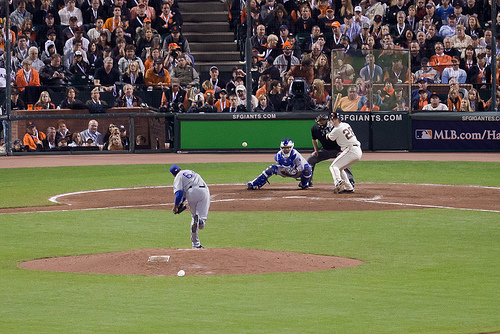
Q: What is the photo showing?
A: It is showing a stadium.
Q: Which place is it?
A: It is a stadium.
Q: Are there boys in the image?
A: No, there are no boys.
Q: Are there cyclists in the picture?
A: No, there are no cyclists.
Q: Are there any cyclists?
A: No, there are no cyclists.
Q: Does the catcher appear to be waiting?
A: Yes, the catcher is waiting.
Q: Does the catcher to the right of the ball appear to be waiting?
A: Yes, the catcher is waiting.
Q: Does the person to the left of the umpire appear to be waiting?
A: Yes, the catcher is waiting.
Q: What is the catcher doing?
A: The catcher is waiting.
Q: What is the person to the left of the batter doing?
A: The catcher is waiting.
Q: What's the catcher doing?
A: The catcher is waiting.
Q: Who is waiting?
A: The catcher is waiting.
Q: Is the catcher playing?
A: No, the catcher is waiting.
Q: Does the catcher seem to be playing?
A: No, the catcher is waiting.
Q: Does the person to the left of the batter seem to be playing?
A: No, the catcher is waiting.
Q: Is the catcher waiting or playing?
A: The catcher is waiting.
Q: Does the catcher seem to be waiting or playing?
A: The catcher is waiting.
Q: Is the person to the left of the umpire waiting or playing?
A: The catcher is waiting.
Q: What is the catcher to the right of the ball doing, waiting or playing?
A: The catcher is waiting.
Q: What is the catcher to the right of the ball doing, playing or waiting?
A: The catcher is waiting.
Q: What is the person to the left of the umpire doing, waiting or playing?
A: The catcher is waiting.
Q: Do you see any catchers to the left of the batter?
A: Yes, there is a catcher to the left of the batter.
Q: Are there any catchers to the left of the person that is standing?
A: Yes, there is a catcher to the left of the batter.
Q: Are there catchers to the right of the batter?
A: No, the catcher is to the left of the batter.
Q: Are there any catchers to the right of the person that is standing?
A: No, the catcher is to the left of the batter.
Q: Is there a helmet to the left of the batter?
A: No, there is a catcher to the left of the batter.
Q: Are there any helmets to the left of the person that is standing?
A: No, there is a catcher to the left of the batter.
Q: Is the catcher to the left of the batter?
A: Yes, the catcher is to the left of the batter.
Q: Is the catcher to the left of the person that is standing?
A: Yes, the catcher is to the left of the batter.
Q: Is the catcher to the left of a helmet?
A: No, the catcher is to the left of the batter.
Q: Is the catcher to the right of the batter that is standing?
A: No, the catcher is to the left of the batter.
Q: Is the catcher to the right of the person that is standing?
A: No, the catcher is to the left of the batter.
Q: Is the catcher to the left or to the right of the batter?
A: The catcher is to the left of the batter.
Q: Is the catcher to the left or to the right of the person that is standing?
A: The catcher is to the left of the batter.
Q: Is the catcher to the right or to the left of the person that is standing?
A: The catcher is to the left of the batter.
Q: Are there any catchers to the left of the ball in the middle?
A: No, the catcher is to the right of the ball.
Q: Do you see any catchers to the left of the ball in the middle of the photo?
A: No, the catcher is to the right of the ball.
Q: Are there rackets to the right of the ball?
A: No, there is a catcher to the right of the ball.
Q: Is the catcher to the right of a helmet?
A: No, the catcher is to the right of the ball.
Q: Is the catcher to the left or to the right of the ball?
A: The catcher is to the right of the ball.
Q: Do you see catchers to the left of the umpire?
A: Yes, there is a catcher to the left of the umpire.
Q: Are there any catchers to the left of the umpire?
A: Yes, there is a catcher to the left of the umpire.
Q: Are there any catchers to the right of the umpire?
A: No, the catcher is to the left of the umpire.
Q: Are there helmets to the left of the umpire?
A: No, there is a catcher to the left of the umpire.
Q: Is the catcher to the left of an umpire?
A: Yes, the catcher is to the left of an umpire.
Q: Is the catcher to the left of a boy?
A: No, the catcher is to the left of an umpire.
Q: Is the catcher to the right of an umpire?
A: No, the catcher is to the left of an umpire.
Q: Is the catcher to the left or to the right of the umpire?
A: The catcher is to the left of the umpire.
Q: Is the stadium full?
A: Yes, the stadium is full.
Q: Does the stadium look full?
A: Yes, the stadium is full.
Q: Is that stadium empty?
A: No, the stadium is full.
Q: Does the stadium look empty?
A: No, the stadium is full.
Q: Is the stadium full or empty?
A: The stadium is full.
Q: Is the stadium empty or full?
A: The stadium is full.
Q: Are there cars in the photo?
A: No, there are no cars.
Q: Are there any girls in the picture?
A: No, there are no girls.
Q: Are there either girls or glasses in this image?
A: No, there are no girls or glasses.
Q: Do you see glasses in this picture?
A: No, there are no glasses.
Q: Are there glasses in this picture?
A: No, there are no glasses.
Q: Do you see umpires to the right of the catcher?
A: Yes, there is an umpire to the right of the catcher.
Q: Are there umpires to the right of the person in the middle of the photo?
A: Yes, there is an umpire to the right of the catcher.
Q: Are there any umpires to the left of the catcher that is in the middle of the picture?
A: No, the umpire is to the right of the catcher.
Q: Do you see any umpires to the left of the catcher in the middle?
A: No, the umpire is to the right of the catcher.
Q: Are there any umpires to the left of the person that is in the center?
A: No, the umpire is to the right of the catcher.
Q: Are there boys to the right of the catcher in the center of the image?
A: No, there is an umpire to the right of the catcher.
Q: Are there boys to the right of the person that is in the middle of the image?
A: No, there is an umpire to the right of the catcher.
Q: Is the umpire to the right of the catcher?
A: Yes, the umpire is to the right of the catcher.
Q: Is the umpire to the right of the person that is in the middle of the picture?
A: Yes, the umpire is to the right of the catcher.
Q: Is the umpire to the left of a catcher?
A: No, the umpire is to the right of a catcher.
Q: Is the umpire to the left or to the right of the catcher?
A: The umpire is to the right of the catcher.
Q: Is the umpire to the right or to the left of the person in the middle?
A: The umpire is to the right of the catcher.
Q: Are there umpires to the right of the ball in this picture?
A: Yes, there is an umpire to the right of the ball.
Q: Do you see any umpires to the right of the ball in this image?
A: Yes, there is an umpire to the right of the ball.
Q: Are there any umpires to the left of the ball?
A: No, the umpire is to the right of the ball.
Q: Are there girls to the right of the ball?
A: No, there is an umpire to the right of the ball.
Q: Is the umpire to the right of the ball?
A: Yes, the umpire is to the right of the ball.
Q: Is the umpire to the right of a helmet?
A: No, the umpire is to the right of the ball.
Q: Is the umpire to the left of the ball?
A: No, the umpire is to the right of the ball.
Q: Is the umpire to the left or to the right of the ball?
A: The umpire is to the right of the ball.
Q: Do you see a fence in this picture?
A: Yes, there is a fence.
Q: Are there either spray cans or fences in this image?
A: Yes, there is a fence.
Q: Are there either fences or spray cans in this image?
A: Yes, there is a fence.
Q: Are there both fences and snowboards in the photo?
A: No, there is a fence but no snowboards.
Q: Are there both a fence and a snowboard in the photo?
A: No, there is a fence but no snowboards.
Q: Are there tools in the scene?
A: No, there are no tools.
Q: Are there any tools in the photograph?
A: No, there are no tools.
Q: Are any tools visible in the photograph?
A: No, there are no tools.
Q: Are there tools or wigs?
A: No, there are no tools or wigs.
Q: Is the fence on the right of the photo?
A: Yes, the fence is on the right of the image.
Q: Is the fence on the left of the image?
A: No, the fence is on the right of the image.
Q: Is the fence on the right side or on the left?
A: The fence is on the right of the image.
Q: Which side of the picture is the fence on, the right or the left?
A: The fence is on the right of the image.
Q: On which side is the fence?
A: The fence is on the right of the image.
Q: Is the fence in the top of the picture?
A: Yes, the fence is in the top of the image.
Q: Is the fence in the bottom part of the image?
A: No, the fence is in the top of the image.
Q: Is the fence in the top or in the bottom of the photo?
A: The fence is in the top of the image.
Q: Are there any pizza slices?
A: No, there are no pizza slices.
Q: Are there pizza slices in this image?
A: No, there are no pizza slices.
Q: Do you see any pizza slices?
A: No, there are no pizza slices.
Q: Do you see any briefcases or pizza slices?
A: No, there are no pizza slices or briefcases.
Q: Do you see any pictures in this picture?
A: No, there are no pictures.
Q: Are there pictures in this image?
A: No, there are no pictures.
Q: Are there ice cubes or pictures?
A: No, there are no pictures or ice cubes.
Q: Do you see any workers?
A: No, there are no workers.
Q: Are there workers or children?
A: No, there are no workers or children.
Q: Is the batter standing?
A: Yes, the batter is standing.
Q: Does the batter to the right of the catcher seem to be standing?
A: Yes, the batter is standing.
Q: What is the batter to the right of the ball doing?
A: The batter is standing.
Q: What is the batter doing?
A: The batter is standing.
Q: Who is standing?
A: The batter is standing.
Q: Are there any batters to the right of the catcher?
A: Yes, there is a batter to the right of the catcher.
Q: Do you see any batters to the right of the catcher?
A: Yes, there is a batter to the right of the catcher.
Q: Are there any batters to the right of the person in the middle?
A: Yes, there is a batter to the right of the catcher.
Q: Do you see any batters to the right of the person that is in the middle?
A: Yes, there is a batter to the right of the catcher.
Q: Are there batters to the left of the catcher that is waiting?
A: No, the batter is to the right of the catcher.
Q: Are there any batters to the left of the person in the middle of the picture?
A: No, the batter is to the right of the catcher.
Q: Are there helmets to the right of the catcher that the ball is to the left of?
A: No, there is a batter to the right of the catcher.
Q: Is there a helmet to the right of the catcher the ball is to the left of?
A: No, there is a batter to the right of the catcher.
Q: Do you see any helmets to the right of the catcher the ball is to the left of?
A: No, there is a batter to the right of the catcher.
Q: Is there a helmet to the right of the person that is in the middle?
A: No, there is a batter to the right of the catcher.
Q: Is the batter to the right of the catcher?
A: Yes, the batter is to the right of the catcher.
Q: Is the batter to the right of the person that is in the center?
A: Yes, the batter is to the right of the catcher.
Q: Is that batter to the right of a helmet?
A: No, the batter is to the right of the catcher.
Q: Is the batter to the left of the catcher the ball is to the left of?
A: No, the batter is to the right of the catcher.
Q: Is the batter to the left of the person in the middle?
A: No, the batter is to the right of the catcher.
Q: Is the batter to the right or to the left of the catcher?
A: The batter is to the right of the catcher.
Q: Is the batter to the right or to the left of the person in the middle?
A: The batter is to the right of the catcher.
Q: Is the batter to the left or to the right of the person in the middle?
A: The batter is to the right of the catcher.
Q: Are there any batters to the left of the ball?
A: No, the batter is to the right of the ball.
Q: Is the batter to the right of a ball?
A: Yes, the batter is to the right of a ball.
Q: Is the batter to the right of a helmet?
A: No, the batter is to the right of a ball.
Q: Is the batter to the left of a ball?
A: No, the batter is to the right of a ball.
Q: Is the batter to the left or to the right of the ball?
A: The batter is to the right of the ball.